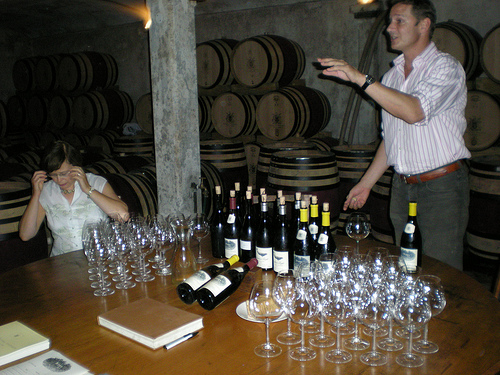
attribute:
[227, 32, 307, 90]
keg — wooden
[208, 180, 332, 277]
bottles — open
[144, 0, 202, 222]
pillar — grey, light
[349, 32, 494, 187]
shirt — striped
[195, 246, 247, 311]
bottle — red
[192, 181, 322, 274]
bottles — wine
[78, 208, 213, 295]
glasses — wine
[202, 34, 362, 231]
barrels — stacked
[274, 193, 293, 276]
wine bottle — red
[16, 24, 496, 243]
barrels — large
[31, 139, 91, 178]
hair — brown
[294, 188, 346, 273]
bottle — wine